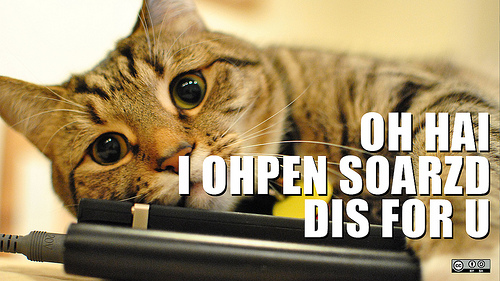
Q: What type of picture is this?
A: A meme.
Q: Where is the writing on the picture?
A: To the right.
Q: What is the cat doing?
A: Laying down.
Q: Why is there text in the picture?
A: To make a joke.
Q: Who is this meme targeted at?
A: Cat lovers.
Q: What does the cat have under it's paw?
A: A phone.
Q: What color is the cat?
A: Brown and white.